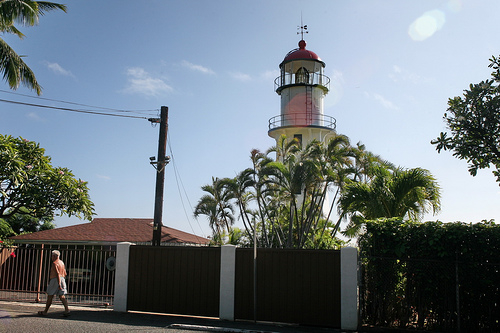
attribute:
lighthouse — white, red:
[267, 41, 358, 247]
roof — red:
[276, 39, 326, 61]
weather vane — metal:
[290, 11, 310, 41]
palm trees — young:
[193, 133, 422, 243]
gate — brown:
[118, 239, 360, 329]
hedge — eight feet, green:
[360, 214, 500, 327]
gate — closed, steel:
[2, 240, 115, 308]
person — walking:
[34, 248, 73, 318]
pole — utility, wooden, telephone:
[151, 103, 172, 243]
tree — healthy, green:
[2, 134, 97, 240]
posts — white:
[111, 240, 131, 313]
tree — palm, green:
[345, 169, 438, 222]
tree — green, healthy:
[1, 2, 68, 97]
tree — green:
[429, 51, 499, 184]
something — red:
[2, 239, 21, 265]